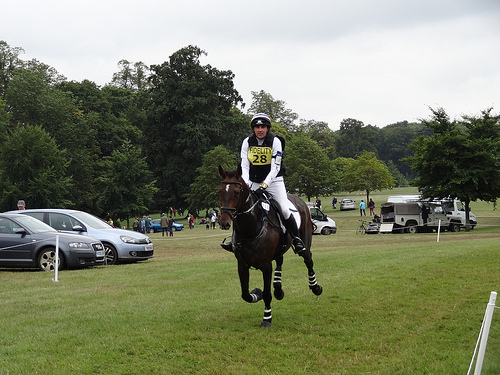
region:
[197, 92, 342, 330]
a man riding a horse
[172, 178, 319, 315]
a horse running in a feild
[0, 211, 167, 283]
two cars parked on the grass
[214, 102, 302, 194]
a man wearing a helet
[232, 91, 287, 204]
a man wearing a black vest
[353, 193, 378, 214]
two people standing in a field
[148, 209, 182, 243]
a blue car parked in a field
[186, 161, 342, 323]
a brown horse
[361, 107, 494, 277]
a white truck parked under a tree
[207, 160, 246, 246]
a horse with a white spot on its face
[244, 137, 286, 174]
yellow sign with black numbers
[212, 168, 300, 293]
a brown horse with a white spot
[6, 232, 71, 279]
a white metal fence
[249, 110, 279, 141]
a person wearing a gray helment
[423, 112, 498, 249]
a tree growing in the field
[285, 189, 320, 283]
a person wearing black boots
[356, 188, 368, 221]
a person wearing a green shirt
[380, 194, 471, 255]
white truck parked beside the fence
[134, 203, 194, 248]
people standing around the field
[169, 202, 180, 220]
a person wearing a red shirt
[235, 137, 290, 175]
Fidelity 28 on label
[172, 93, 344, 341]
This man is rider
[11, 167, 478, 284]
Plenty of cars are parked here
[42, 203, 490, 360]
The grass has been cut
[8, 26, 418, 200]
Trees are in the background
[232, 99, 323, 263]
This man is looking into the camera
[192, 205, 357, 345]
The horse has stripes above leg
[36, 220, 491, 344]
Fences on the side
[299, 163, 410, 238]
People are wondering around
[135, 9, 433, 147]
The sky is cloudy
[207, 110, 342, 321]
A man riding a horse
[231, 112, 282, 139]
A man's head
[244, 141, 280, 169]
A Fidelity 28 bib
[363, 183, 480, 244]
A camper trailer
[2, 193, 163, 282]
Two cars parked on grass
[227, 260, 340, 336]
a horse's 4 legs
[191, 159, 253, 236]
A horse's head with a white blaze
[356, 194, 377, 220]
Two people standing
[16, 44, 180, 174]
A gathering of green trees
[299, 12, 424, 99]
A section of cloudy sky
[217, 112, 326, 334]
man riding a horse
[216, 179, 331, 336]
black horse trotting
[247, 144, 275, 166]
yellow FIDELITY 28 shirt tag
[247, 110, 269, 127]
black and white riding hat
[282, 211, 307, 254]
black horse riding boots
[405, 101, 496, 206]
tall trees with green leaves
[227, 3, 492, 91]
mostly cloudy skies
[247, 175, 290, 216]
white riding pants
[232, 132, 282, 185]
white and black riding shirt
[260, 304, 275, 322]
white and black horse ankle support